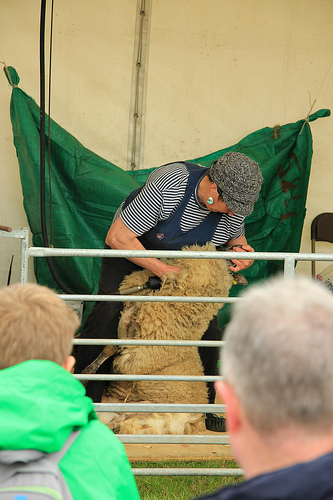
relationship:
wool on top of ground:
[89, 397, 209, 435] [91, 412, 248, 500]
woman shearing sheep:
[72, 148, 265, 433] [95, 240, 248, 433]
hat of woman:
[205, 151, 267, 219] [72, 148, 265, 433]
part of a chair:
[309, 210, 332, 246] [310, 210, 333, 275]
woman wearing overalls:
[72, 148, 265, 433] [74, 160, 229, 405]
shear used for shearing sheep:
[117, 275, 164, 295] [95, 240, 248, 433]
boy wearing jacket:
[0, 357, 147, 498] [0, 357, 147, 498]